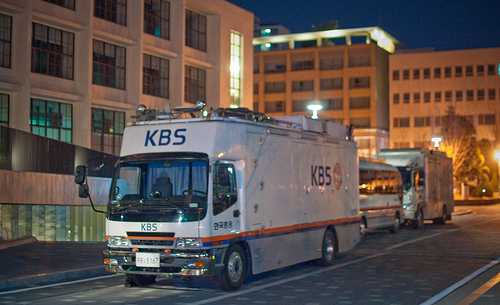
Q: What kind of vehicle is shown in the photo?
A: Truck.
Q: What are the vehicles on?
A: The street.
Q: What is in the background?
A: Buildings.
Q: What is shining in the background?
A: Street lights.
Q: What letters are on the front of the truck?
A: KBS.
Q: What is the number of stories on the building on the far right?
A: Five.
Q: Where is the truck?
A: On the street.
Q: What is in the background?
A: Buildings.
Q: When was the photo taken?
A: Night.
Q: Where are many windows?
A: On buildings.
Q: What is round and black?
A: Tires.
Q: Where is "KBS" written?
A: On the truck.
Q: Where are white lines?
A: On the street.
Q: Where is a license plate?
A: In front of the truck.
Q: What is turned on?
A: Street lamps.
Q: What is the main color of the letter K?
A: Blue.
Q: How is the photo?
A: Clear.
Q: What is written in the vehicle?
A: Kbs.